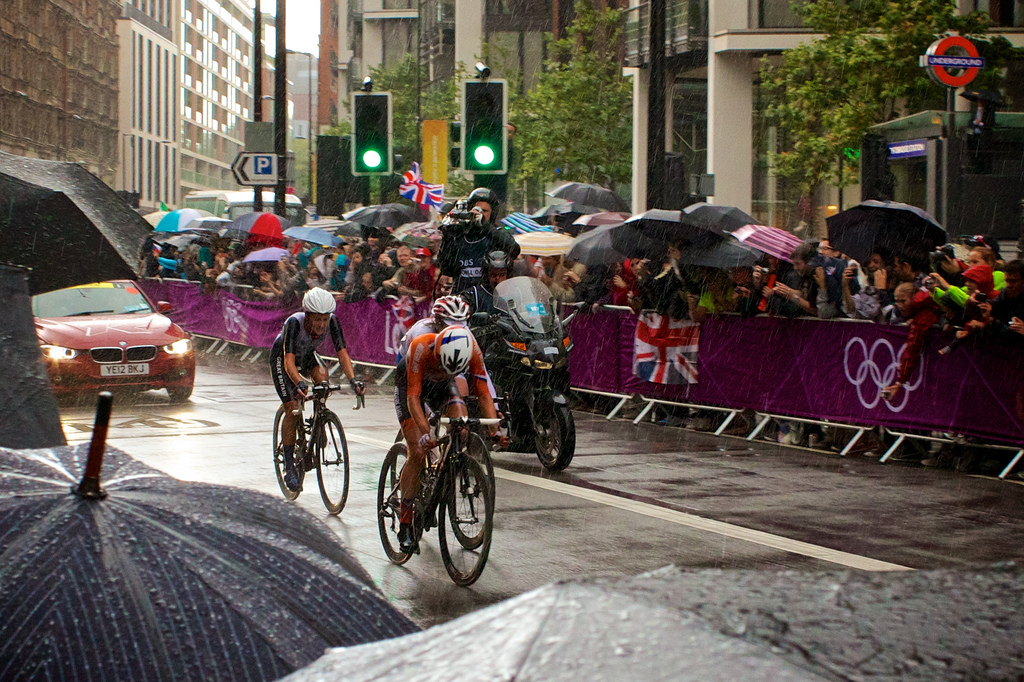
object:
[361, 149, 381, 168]
light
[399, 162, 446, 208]
flag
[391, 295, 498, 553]
man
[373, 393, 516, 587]
bike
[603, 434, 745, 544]
road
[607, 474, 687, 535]
line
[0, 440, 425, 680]
umbrella